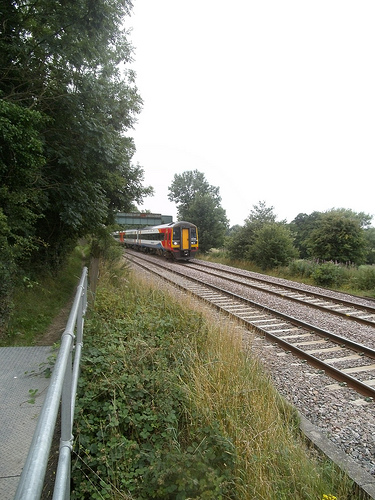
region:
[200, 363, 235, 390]
yellow grass on the side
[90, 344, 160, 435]
over grown green shrub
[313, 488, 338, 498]
small cluster of yellow flower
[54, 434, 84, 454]
silver joint on railing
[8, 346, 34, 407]
small silver pavement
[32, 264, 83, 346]
dirt path at edge of train track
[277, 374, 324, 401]
gray gravel in train track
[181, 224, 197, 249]
yellow door on front of train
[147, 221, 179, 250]
red color on side of train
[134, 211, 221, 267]
train on the railroad track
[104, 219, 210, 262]
train on the tracks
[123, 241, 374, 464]
two parallel train tracks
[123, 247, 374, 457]
gravel on the tracks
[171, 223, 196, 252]
front of the train is black and yellow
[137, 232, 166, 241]
row of windows on the side of the train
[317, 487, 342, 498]
yellow flower on the grass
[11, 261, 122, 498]
silver railing in the grass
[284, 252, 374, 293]
three green bushes by the train tracks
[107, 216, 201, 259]
white, red, and blue train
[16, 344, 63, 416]
green leaves on the other side of the railing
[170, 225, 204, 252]
front car of passenger train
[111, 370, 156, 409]
bunch of green clover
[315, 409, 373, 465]
group of pebbles near tracks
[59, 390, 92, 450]
metal rail next to tracks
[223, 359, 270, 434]
brown and yellow weeds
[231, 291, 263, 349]
set of train tracks on left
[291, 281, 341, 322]
set of tracks on right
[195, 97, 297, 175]
sky is very bright out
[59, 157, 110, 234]
dark green leaves on tree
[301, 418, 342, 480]
concrete barrier near tracks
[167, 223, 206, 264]
train on the track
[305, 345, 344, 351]
railroad tie on track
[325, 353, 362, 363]
railroad tie on track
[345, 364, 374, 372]
railroad tie on track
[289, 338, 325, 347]
railroad tie on track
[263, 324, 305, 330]
railroad tie on track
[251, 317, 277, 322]
railroad tie on track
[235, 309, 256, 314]
railroad tie on track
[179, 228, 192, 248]
Yellow door on train.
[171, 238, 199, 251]
Lights on back of train.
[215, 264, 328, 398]
Gravel under and next to tracks.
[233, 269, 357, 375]
2 sets of tracks next to each other.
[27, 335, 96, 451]
Metal railing near tracks.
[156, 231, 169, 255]
Red coloring on train.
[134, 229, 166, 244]
Windows a long side of train.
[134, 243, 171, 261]
Wheels on train are black.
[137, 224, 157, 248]
White section on train.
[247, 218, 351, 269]
Trees and bushes on side of tracks.